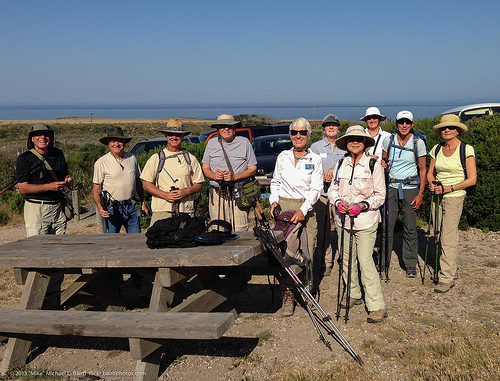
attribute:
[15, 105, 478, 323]
people — posing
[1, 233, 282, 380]
table — wooden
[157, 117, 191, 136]
hat — brown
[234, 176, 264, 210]
bag — green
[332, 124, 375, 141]
hat — white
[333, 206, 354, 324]
poles — used, pointed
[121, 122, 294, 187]
vehicles — parked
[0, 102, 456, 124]
water — large, calm, wide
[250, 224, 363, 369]
equipment — leaning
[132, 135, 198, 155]
car — parked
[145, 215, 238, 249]
bag — black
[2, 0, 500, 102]
sky — blue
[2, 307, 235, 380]
bench — wooden, large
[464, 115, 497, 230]
bush — large, green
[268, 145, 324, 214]
shirt — white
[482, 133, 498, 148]
leaves — green